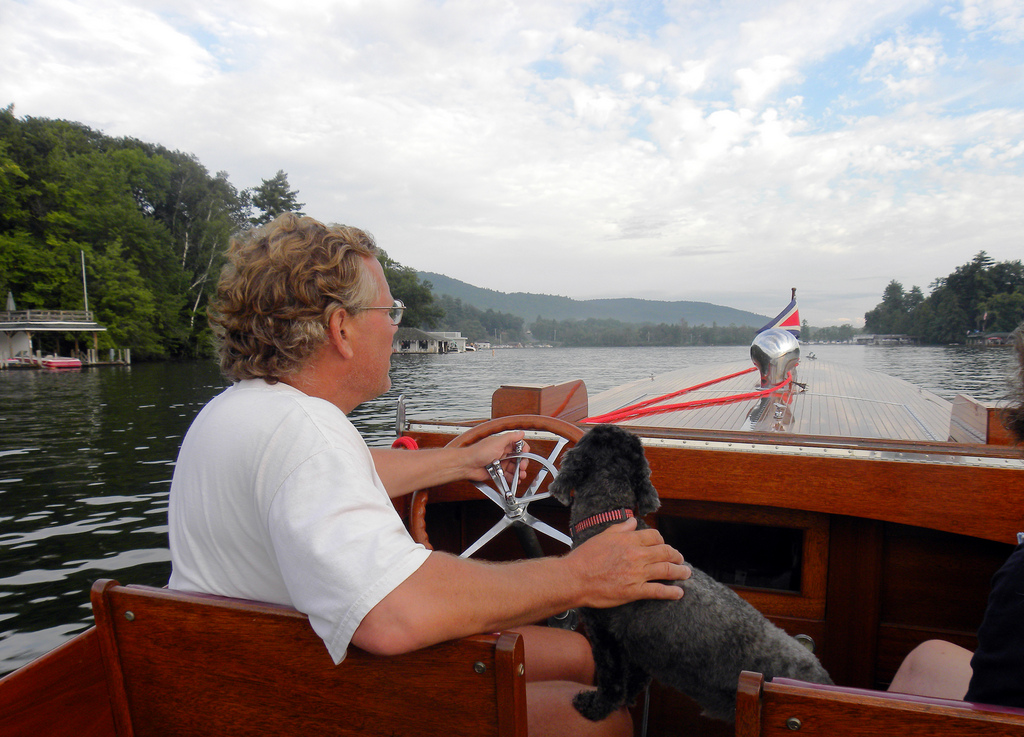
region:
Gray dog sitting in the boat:
[540, 413, 850, 723]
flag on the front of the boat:
[749, 291, 806, 333]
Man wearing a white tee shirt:
[132, 364, 440, 663]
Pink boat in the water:
[37, 347, 79, 368]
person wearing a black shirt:
[955, 518, 1022, 714]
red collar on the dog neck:
[562, 500, 640, 529]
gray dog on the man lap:
[540, 401, 828, 734]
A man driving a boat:
[163, 218, 694, 658]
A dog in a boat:
[549, 420, 832, 721]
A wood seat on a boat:
[90, 572, 528, 732]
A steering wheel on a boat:
[412, 417, 609, 564]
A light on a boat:
[745, 323, 806, 394]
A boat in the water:
[5, 288, 1021, 725]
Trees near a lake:
[6, 104, 247, 348]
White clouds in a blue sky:
[0, 1, 1019, 330]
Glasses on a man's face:
[349, 294, 413, 320]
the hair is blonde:
[196, 206, 365, 393]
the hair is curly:
[217, 217, 358, 372]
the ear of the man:
[319, 291, 364, 364]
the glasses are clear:
[366, 287, 411, 332]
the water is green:
[19, 344, 1021, 567]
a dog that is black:
[556, 432, 807, 707]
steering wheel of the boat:
[403, 414, 616, 595]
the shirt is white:
[177, 391, 384, 617]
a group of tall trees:
[847, 263, 949, 328]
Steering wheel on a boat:
[408, 410, 595, 560]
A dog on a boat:
[545, 420, 827, 733]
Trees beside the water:
[1, 104, 451, 358]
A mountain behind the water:
[416, 263, 777, 330]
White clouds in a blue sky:
[569, 86, 807, 169]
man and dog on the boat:
[168, 206, 876, 709]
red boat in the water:
[32, 341, 89, 379]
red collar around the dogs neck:
[574, 503, 635, 530]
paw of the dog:
[560, 672, 618, 721]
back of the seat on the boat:
[106, 591, 296, 699]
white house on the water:
[400, 320, 468, 356]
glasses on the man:
[140, 189, 406, 633]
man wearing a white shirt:
[179, 181, 465, 656]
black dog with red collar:
[527, 362, 819, 672]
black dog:
[536, 393, 767, 682]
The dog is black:
[532, 420, 852, 725]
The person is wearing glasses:
[352, 289, 414, 337]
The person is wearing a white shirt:
[156, 359, 435, 667]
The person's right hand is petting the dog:
[564, 514, 705, 614]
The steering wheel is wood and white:
[409, 398, 637, 610]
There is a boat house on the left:
[1, 235, 129, 379]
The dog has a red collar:
[555, 494, 639, 540]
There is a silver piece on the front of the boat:
[742, 315, 812, 401]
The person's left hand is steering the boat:
[459, 420, 545, 497]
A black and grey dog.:
[547, 422, 838, 724]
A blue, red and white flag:
[754, 302, 802, 338]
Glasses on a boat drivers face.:
[340, 294, 405, 326]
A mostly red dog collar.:
[566, 505, 636, 534]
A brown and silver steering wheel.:
[413, 410, 588, 559]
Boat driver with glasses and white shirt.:
[170, 210, 690, 735]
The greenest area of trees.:
[3, 103, 247, 356]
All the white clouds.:
[0, 5, 1022, 319]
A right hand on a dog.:
[575, 518, 690, 607]